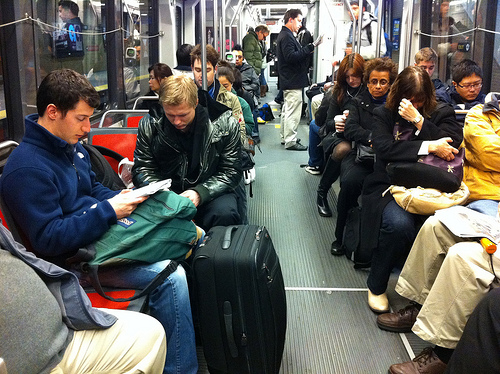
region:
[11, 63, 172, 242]
a man reading a paper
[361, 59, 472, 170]
person sleeping on the train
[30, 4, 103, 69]
a reflection in the window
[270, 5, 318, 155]
a man standing in the aisle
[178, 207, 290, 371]
black suitcase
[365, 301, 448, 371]
a pair of feet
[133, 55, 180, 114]
a woman looking out the window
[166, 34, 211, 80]
a passenger riding backwards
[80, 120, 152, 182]
orange seat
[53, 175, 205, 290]
a blue duffle bag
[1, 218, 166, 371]
a pretty chubby man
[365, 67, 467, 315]
white shoe out of season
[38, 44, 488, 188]
majority are faces down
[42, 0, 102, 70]
someone outside or a reflection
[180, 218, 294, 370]
the suitcase looks stuffed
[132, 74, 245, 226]
a jacket and an ascot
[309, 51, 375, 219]
a woman wearing hosiery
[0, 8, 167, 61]
pull cord for immediate stop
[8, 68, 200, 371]
man reading instead of using phone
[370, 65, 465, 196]
praying or weeping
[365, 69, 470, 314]
Woman on the right is upset.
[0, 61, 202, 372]
Man in blue coat holds a backpack.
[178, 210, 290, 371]
Black luggage sits upright in aisle.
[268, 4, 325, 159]
Man is standing on the subway.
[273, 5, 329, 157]
Man reads newspaper on the subway.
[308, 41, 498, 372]
Seats on the right are full.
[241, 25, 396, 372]
The aisle is clean.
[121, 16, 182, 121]
Woman watches out the window.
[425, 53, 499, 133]
Boy in glasses studies on way home.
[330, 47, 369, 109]
woman with red brown hair needs her darker roots done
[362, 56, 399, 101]
woman on bus looks exhausted, has circles under her eyes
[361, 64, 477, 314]
woman, head down, sad or tired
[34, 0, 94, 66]
man reading newspaper reflected in window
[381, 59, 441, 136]
woman holds hand to her face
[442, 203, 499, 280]
man carries mini-umbrella [or pingpong paddle] with yellow handle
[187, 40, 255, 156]
seated man is very tall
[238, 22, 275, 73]
middle aged man wears puffy army colored jacket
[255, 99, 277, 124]
someone stuck bright blue baggage in the aisle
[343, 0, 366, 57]
man's eye looks from between two metal poles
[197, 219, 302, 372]
a piece of luggage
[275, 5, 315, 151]
a man is standing in the aisle of a bus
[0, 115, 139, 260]
man is wearing a blue sweater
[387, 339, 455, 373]
brown leather shoe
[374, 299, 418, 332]
brown leather shoe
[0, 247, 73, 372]
someone's belly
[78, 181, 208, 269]
man has green backpack in his lap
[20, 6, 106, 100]
window of the bus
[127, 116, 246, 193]
a black leather jacket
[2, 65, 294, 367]
man in blue sweater is reading a book